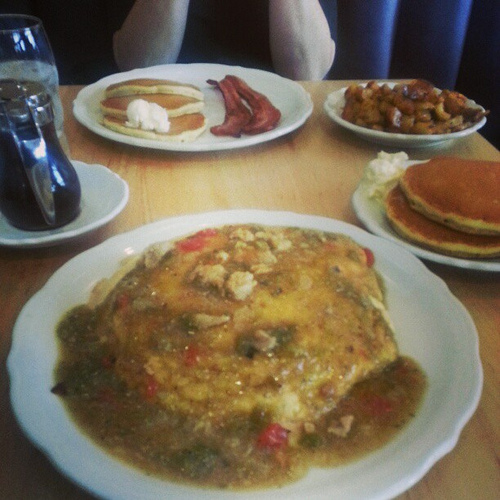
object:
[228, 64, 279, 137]
meat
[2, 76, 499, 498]
table